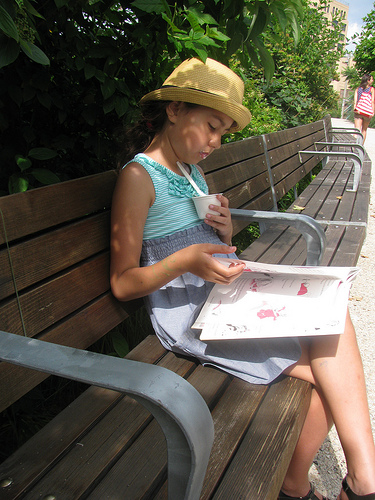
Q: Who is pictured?
A: A girl.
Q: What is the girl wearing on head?
A: Hat.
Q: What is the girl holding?
A: Container with spoon.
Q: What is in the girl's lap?
A: Book.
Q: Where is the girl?
A: On a bench.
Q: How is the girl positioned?
A: Sitting.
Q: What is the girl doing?
A: Reading.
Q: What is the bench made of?
A: Wood.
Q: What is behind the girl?
A: Bushes.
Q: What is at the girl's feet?
A: Gravel.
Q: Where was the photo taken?
A: In a park.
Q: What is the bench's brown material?
A: Wood.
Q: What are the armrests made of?
A: Metal.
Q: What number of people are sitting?
A: One.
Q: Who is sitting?
A: A girl.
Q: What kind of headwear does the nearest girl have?
A: A hat.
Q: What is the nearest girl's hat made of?
A: Straw.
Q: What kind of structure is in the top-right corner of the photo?
A: A building.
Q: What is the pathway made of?
A: Gravel.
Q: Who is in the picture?
A: A girl.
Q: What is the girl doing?
A: Reading a book.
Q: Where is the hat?
A: On the girl's head.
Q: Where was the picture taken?
A: In a park.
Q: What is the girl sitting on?
A: A bench.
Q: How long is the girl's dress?
A: Mini.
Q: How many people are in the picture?
A: 2.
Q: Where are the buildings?
A: Background.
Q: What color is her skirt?
A: Blue.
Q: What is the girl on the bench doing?
A: Reading.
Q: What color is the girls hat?
A: Yellow.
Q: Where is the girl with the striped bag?
A: In the background.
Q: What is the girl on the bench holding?
A: A cup.